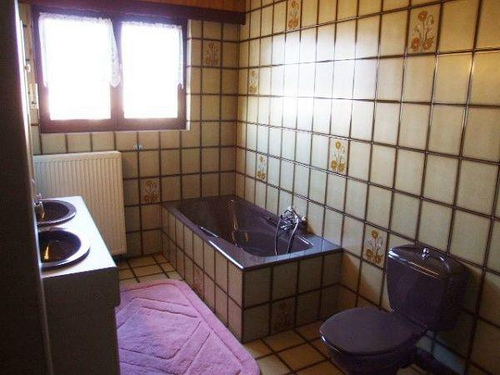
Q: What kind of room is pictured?
A: It is a bathroom.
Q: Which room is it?
A: It is a bathroom.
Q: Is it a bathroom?
A: Yes, it is a bathroom.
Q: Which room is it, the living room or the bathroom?
A: It is the bathroom.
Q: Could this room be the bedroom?
A: No, it is the bathroom.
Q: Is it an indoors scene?
A: Yes, it is indoors.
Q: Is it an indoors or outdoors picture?
A: It is indoors.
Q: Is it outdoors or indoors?
A: It is indoors.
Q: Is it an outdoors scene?
A: No, it is indoors.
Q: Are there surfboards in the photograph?
A: No, there are no surfboards.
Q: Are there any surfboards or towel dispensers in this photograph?
A: No, there are no surfboards or towel dispensers.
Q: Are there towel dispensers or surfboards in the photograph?
A: No, there are no surfboards or towel dispensers.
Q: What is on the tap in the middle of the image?
A: The water hose is on the tap.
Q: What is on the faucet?
A: The water hose is on the tap.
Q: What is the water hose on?
A: The water hose is on the tap.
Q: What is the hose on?
A: The water hose is on the tap.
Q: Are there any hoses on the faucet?
A: Yes, there is a hose on the faucet.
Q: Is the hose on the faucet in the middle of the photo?
A: Yes, the hose is on the faucet.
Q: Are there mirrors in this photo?
A: No, there are no mirrors.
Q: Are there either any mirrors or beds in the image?
A: No, there are no mirrors or beds.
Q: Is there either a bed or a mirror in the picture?
A: No, there are no mirrors or beds.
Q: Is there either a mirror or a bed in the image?
A: No, there are no mirrors or beds.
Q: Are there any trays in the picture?
A: No, there are no trays.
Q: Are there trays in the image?
A: No, there are no trays.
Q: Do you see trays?
A: No, there are no trays.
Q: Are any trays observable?
A: No, there are no trays.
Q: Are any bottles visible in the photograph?
A: No, there are no bottles.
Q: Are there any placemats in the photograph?
A: No, there are no placemats.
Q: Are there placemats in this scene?
A: No, there are no placemats.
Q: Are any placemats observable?
A: No, there are no placemats.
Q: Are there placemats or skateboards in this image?
A: No, there are no placemats or skateboards.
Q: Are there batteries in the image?
A: No, there are no batteries.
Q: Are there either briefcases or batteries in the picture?
A: No, there are no batteries or briefcases.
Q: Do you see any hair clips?
A: No, there are no hair clips.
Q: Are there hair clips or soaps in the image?
A: No, there are no hair clips or soaps.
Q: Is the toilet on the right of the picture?
A: Yes, the toilet is on the right of the image.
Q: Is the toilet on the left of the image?
A: No, the toilet is on the right of the image.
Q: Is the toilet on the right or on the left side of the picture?
A: The toilet is on the right of the image.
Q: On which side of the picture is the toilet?
A: The toilet is on the right of the image.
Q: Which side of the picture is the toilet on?
A: The toilet is on the right of the image.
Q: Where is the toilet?
A: The toilet is in the bathroom.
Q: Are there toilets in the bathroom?
A: Yes, there is a toilet in the bathroom.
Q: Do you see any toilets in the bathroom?
A: Yes, there is a toilet in the bathroom.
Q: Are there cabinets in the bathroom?
A: No, there is a toilet in the bathroom.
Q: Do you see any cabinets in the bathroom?
A: No, there is a toilet in the bathroom.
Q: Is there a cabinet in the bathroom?
A: No, there is a toilet in the bathroom.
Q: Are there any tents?
A: No, there are no tents.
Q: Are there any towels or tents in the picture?
A: No, there are no tents or towels.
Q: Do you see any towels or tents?
A: No, there are no tents or towels.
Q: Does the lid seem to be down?
A: Yes, the lid is down.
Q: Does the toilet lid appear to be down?
A: Yes, the lid is down.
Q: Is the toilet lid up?
A: No, the lid is down.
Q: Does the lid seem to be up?
A: No, the lid is down.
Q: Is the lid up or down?
A: The lid is down.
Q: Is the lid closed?
A: Yes, the lid is closed.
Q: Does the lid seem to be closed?
A: Yes, the lid is closed.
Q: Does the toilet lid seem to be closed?
A: Yes, the lid is closed.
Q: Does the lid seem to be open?
A: No, the lid is closed.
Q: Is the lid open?
A: No, the lid is closed.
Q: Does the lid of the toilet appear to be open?
A: No, the lid is closed.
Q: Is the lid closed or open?
A: The lid is closed.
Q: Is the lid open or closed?
A: The lid is closed.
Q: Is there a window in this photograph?
A: Yes, there are windows.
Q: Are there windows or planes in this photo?
A: Yes, there are windows.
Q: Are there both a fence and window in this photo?
A: No, there are windows but no fences.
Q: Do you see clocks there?
A: No, there are no clocks.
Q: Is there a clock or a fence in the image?
A: No, there are no clocks or fences.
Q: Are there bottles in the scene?
A: No, there are no bottles.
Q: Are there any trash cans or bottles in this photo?
A: No, there are no bottles or trash cans.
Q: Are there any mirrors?
A: No, there are no mirrors.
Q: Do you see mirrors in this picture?
A: No, there are no mirrors.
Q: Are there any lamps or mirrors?
A: No, there are no mirrors or lamps.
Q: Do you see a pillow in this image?
A: No, there are no pillows.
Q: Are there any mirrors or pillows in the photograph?
A: No, there are no pillows or mirrors.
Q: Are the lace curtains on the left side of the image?
A: Yes, the curtains are on the left of the image.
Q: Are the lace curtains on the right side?
A: No, the curtains are on the left of the image.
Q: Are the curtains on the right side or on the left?
A: The curtains are on the left of the image.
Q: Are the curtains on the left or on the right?
A: The curtains are on the left of the image.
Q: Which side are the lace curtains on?
A: The curtains are on the left of the image.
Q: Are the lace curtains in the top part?
A: Yes, the curtains are in the top of the image.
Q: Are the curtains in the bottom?
A: No, the curtains are in the top of the image.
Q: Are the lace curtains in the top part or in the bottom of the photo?
A: The curtains are in the top of the image.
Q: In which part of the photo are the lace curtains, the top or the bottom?
A: The curtains are in the top of the image.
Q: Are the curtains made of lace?
A: Yes, the curtains are made of lace.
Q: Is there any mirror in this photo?
A: No, there are no mirrors.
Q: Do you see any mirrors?
A: No, there are no mirrors.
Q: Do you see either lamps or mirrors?
A: No, there are no mirrors or lamps.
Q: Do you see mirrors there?
A: No, there are no mirrors.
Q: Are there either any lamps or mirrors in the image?
A: No, there are no mirrors or lamps.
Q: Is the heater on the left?
A: Yes, the heater is on the left of the image.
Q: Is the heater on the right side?
A: No, the heater is on the left of the image.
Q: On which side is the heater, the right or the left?
A: The heater is on the left of the image.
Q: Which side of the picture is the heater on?
A: The heater is on the left of the image.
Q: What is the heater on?
A: The heater is on the wall.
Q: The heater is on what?
A: The heater is on the wall.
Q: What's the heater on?
A: The heater is on the wall.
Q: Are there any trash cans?
A: No, there are no trash cans.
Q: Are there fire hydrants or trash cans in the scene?
A: No, there are no trash cans or fire hydrants.